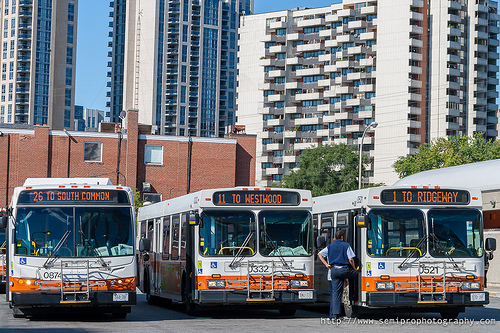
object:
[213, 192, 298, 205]
digital board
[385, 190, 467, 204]
digital board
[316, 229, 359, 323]
man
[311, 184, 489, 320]
bus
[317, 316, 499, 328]
website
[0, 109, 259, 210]
building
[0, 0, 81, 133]
buildings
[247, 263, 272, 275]
number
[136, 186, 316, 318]
bus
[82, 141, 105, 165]
windows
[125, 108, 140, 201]
chimney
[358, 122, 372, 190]
pole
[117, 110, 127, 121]
satellite dish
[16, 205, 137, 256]
window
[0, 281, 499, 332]
road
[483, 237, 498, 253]
side mirror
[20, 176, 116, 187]
top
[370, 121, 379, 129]
streetlight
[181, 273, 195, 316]
front wheel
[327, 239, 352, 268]
sweater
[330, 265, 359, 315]
pants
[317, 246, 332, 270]
left arm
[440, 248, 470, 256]
wheel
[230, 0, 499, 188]
buildings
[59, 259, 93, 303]
bike rack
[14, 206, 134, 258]
windshield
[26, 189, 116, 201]
digital board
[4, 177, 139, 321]
bus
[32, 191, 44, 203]
number 26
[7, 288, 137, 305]
bumper